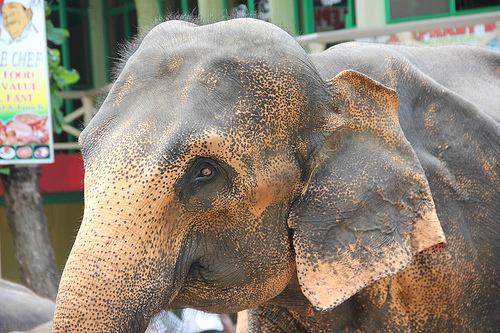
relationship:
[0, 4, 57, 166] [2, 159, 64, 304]
sign on tree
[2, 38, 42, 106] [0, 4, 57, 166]
words on sign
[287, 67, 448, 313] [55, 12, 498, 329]
ear on elephant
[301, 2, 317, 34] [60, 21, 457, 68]
frame around windows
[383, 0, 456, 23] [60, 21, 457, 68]
window around windows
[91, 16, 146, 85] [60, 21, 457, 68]
window around windows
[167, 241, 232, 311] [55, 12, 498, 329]
mouth of elephant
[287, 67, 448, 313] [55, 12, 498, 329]
ear of elephant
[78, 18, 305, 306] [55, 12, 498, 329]
head of elephant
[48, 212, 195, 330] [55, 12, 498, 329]
nose of elephant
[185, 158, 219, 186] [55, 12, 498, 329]
eye of elephant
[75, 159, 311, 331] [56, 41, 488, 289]
mouth of elephant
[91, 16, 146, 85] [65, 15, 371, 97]
window of building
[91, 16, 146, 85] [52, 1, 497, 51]
window of building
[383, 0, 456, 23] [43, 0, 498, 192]
window of building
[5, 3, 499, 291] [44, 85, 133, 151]
building with railing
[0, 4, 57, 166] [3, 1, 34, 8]
sign with hat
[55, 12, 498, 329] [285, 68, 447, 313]
elephant has ears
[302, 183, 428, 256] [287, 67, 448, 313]
veins on ear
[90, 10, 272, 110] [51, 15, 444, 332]
hair on head